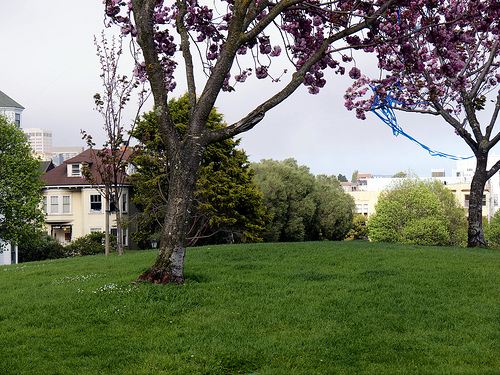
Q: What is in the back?
A: Houses.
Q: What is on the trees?
A: Purple flowers.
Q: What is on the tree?
A: A kite.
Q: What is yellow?
A: The house.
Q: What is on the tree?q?
A: Bark.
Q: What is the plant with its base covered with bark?
A: Tree.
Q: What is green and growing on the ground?
A: Grass.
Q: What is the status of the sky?
A: Clear.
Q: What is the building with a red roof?
A: House.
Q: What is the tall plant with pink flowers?
A: A tree.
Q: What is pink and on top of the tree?
A: Flowers.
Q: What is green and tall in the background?
A: Trees.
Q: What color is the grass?
A: Green.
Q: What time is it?
A: Daytime.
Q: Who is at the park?
A: No one.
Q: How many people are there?
A: None.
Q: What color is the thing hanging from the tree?
A: Blue.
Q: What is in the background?
A: Trees.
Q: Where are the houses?
A: In the back.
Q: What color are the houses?
A: White.